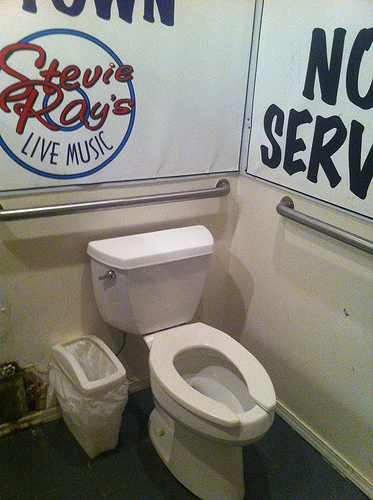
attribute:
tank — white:
[87, 220, 218, 332]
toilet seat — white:
[151, 321, 278, 429]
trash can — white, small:
[50, 331, 126, 463]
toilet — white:
[86, 223, 292, 499]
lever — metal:
[96, 269, 117, 284]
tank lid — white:
[85, 217, 216, 270]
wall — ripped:
[1, 2, 257, 427]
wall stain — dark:
[0, 376, 37, 418]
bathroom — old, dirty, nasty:
[1, 2, 365, 490]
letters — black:
[264, 23, 371, 204]